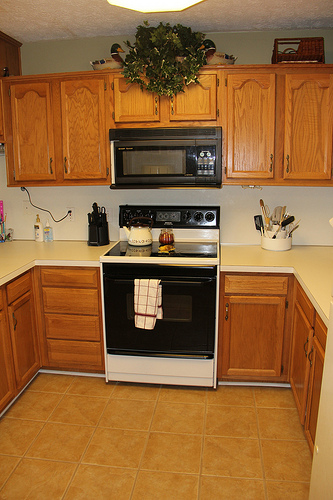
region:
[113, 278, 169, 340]
a towel hanging on a oven handle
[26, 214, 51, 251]
two pump bottles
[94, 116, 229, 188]
a black microwave oven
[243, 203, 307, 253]
a container with several utensils stored in it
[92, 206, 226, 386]
a black and white oven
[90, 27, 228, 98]
a indoor plant on a cabinet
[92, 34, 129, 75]
a statue of a duck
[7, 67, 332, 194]
oak kitchen cabinets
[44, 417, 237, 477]
a light brown tile floor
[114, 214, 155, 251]
a tea kettle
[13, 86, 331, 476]
Picture of a kitchen.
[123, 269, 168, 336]
Striped kitchen towel.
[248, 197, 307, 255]
White utensil carousel.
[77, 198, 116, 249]
Black kitchen carousel.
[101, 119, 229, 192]
Black microwave mounted on cabinet.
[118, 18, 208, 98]
Green plant on top of cabinet.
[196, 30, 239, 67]
Figure of mallard duck on right side.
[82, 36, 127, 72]
Figure of mallard duck on left side.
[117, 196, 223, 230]
Black ontrol panel for stove.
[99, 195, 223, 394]
White and black stove.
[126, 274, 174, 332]
kitchen hand towel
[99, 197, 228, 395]
black and white oven with cooktop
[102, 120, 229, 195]
over the stove mounted microwave oven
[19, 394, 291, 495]
gold tiled kitchen floor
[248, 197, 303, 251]
white kitchen utensil holder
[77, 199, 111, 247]
black kitchen utensil holder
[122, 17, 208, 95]
artificial greenery decoration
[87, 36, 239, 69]
pair of mallard duck decoys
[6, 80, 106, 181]
oak kitchen cabinetry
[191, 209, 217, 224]
stove top controller knobs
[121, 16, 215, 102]
A PLANT ON TOP OF CABINETS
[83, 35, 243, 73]
TWO DUCKS ON TOP OF THE CABINETS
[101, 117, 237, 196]
A MICROWAVE UNDER KITCHEN CABINETS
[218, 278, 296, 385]
UNDER THE COUNTER KITCHEN CABINET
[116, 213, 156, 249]
A TEA POT ON TOP OF THE STOVE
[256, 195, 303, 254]
A CONTAINER OF KITCHEN TOOLS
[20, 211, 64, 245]
HAND LOTION ON THE COUNTER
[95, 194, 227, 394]
A KITCHEN STOVE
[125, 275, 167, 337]
A KITCHEN TOWEL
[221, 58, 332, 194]
BROWN KITCHEN CABINETS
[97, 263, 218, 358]
Black face of the stove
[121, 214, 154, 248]
White tea pot on the stove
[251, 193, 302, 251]
Utensil holder on top of the counter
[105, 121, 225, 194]
Microwave above the stove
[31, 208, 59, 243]
pump bottles on the counter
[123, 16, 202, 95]
Plant on the cupboards above the stove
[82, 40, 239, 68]
Ducks next to the plant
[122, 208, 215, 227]
Dials on the back of the stove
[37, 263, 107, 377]
Four drawers to the left of the stove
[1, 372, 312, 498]
The tiled floor